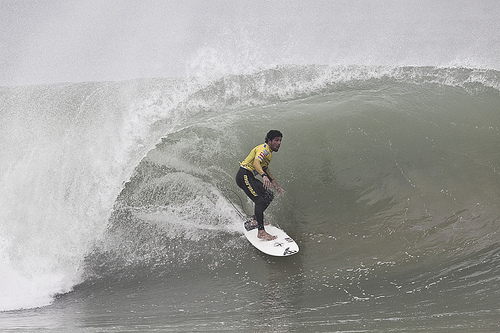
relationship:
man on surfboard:
[236, 129, 282, 241] [239, 220, 302, 261]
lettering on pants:
[243, 170, 262, 201] [236, 163, 276, 232]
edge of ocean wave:
[0, 60, 499, 100] [12, 63, 499, 331]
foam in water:
[4, 56, 230, 317] [12, 61, 497, 331]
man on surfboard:
[236, 129, 282, 241] [204, 187, 300, 256]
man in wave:
[236, 129, 282, 241] [0, 52, 250, 322]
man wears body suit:
[239, 130, 282, 241] [234, 143, 275, 230]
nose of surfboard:
[281, 246, 301, 260] [238, 215, 298, 258]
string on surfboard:
[222, 196, 248, 230] [210, 183, 294, 261]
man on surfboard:
[236, 129, 282, 241] [238, 215, 298, 258]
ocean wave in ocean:
[49, 58, 500, 331] [4, 8, 497, 327]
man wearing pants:
[239, 130, 282, 241] [231, 167, 271, 225]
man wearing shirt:
[236, 129, 282, 241] [236, 138, 276, 174]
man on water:
[236, 129, 282, 241] [12, 61, 497, 331]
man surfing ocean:
[236, 129, 282, 241] [4, 76, 494, 326]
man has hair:
[236, 129, 282, 241] [265, 128, 283, 144]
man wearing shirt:
[236, 129, 282, 241] [241, 143, 273, 175]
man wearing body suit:
[236, 129, 282, 241] [235, 142, 277, 232]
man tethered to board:
[236, 129, 282, 241] [242, 216, 300, 256]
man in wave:
[236, 129, 282, 241] [3, 60, 499, 331]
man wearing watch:
[236, 129, 282, 241] [258, 170, 268, 179]